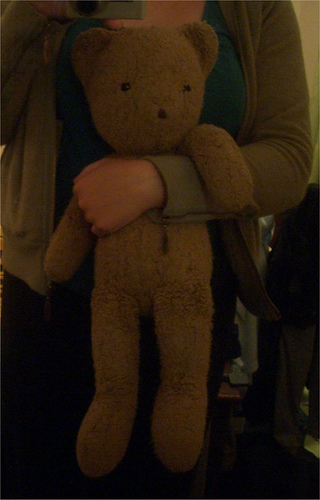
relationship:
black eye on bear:
[183, 83, 192, 91] [43, 21, 253, 478]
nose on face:
[150, 101, 174, 130] [92, 42, 201, 176]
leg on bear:
[155, 288, 214, 386] [143, 72, 206, 141]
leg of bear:
[149, 288, 211, 475] [43, 21, 253, 478]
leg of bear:
[75, 286, 140, 478] [43, 21, 253, 478]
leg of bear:
[155, 288, 214, 386] [43, 21, 253, 478]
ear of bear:
[68, 26, 114, 83] [43, 21, 253, 478]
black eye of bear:
[183, 85, 190, 90] [43, 21, 253, 478]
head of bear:
[73, 18, 220, 154] [88, 28, 201, 73]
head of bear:
[75, 18, 210, 152] [45, 19, 260, 477]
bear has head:
[76, 36, 267, 367] [73, 12, 220, 151]